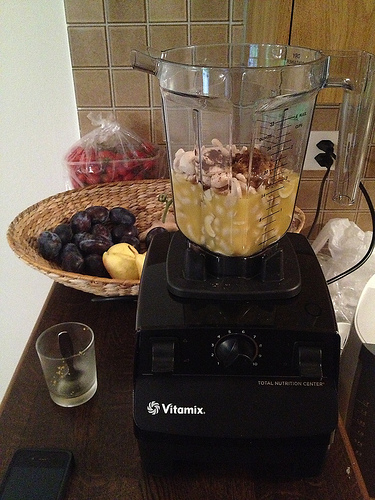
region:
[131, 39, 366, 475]
blender full of juice and food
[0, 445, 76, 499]
black cell phone on the table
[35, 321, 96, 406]
clear glass on the table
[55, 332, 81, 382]
metal spoon in the glass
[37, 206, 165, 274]
grapes in the wicker basket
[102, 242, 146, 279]
pears in the wicker basket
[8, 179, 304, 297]
wicker basket full of fruit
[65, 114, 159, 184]
bag full of grape tomatos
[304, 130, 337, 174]
white electrical outlet on the wall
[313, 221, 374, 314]
empty plastic bags on the table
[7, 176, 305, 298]
a wicker bowl full of fruit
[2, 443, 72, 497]
a black cell phone sitting on the table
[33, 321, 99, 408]
a glass sitting on the table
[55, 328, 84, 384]
a spoon sitting in the glass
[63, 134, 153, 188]
a bag filled with berries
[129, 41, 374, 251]
the glass on the top of the blender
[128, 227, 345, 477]
the bottom half of the blender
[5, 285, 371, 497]
the table the food and blende are sitting on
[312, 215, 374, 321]
a trash bag sitting by the table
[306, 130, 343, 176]
a wall plug with two plugs in it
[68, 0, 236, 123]
tiles on the wall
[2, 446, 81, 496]
a cell phone on the table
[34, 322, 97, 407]
a glass on the table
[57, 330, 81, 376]
a spoon in the glass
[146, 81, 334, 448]
a blender on the table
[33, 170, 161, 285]
a basket of fruit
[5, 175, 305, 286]
a basket on the table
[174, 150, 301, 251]
food in the blender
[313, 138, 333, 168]
cords plugged into the wall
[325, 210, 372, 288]
a bag on the table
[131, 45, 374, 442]
Mixer on dark brown counter.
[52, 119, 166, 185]
Clear plastic bag with red cherry tomatoes.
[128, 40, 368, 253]
Clear mixer pitcher half filled food.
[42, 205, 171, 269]
A bunch of dark plums in basket.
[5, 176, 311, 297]
Light brown wicker basket with fruit in it.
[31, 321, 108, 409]
Dirty clear glass on counter.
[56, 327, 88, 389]
Metal spoon in dirty glass.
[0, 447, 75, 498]
Black smartphone on brown counter.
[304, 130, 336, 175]
Wall socket with two black plugs in it.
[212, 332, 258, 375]
Black dial on black and clear mixer.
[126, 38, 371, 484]
A blender with food in it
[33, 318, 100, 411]
A glass with a spoon in it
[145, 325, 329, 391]
The controls of a blender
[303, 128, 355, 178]
A wall plug with two plugs in it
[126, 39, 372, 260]
The cup of a blender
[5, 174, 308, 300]
A basket with fruit in it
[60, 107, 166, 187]
A plastic bag with berries in it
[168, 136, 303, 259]
food in a blender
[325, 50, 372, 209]
The handle of a blender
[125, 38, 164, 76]
The pour spout of a blender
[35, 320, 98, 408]
small spoon in dirty glass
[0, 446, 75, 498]
black cellphone on top of table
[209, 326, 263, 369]
white numbers around black dial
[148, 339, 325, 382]
two black flip switches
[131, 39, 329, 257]
mushrooms and soup inside plastic pitcher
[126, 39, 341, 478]
pitcher on a black base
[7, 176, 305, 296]
light brown wicker basket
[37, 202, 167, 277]
bunch of purple grapes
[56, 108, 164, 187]
cherry tomatoes in plastic bag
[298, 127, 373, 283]
two black power cords hooked into outlet